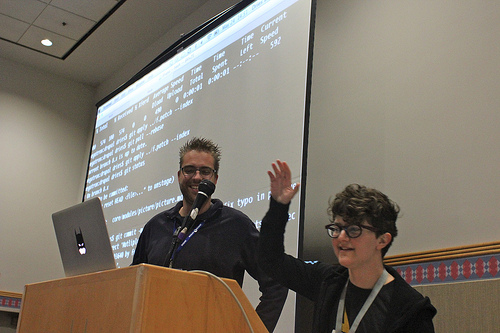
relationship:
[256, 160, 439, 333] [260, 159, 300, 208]
boy has hand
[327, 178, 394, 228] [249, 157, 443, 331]
hair on boy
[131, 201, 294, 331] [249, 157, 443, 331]
shirt on boy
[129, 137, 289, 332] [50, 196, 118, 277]
man behind laptop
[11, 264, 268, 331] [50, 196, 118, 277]
podium beneath laptop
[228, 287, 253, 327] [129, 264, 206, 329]
wire on top of podium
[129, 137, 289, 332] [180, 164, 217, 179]
man wearing glasses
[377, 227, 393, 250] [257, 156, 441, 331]
left ear of person